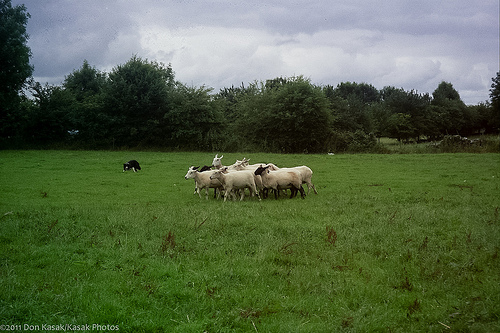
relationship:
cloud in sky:
[0, 0, 500, 82] [0, 1, 495, 108]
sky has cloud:
[0, 1, 495, 108] [383, 48, 449, 93]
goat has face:
[209, 167, 262, 202] [249, 164, 266, 174]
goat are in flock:
[184, 166, 226, 200] [182, 152, 319, 202]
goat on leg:
[209, 167, 262, 202] [223, 187, 229, 199]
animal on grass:
[117, 148, 153, 178] [24, 162, 471, 290]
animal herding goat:
[121, 160, 142, 172] [266, 162, 318, 194]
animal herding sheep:
[121, 160, 142, 172] [210, 166, 260, 200]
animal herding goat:
[121, 160, 142, 172] [254, 162, 306, 200]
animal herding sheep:
[121, 160, 142, 172] [292, 163, 313, 185]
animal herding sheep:
[121, 160, 142, 172] [210, 153, 225, 168]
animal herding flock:
[121, 160, 142, 172] [181, 152, 321, 202]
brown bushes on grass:
[154, 227, 185, 257] [5, 149, 495, 326]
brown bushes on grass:
[324, 223, 343, 250] [5, 149, 495, 326]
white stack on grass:
[325, 149, 338, 163] [328, 167, 470, 306]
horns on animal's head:
[211, 153, 224, 159] [205, 151, 227, 169]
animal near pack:
[118, 155, 143, 175] [183, 153, 318, 203]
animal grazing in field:
[121, 160, 142, 172] [1, 148, 499, 331]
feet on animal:
[120, 166, 141, 188] [113, 147, 142, 179]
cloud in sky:
[246, 51, 393, 82] [0, 1, 495, 108]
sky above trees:
[0, 1, 495, 108] [105, 60, 340, 132]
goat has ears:
[211, 153, 230, 169] [212, 153, 224, 161]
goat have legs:
[184, 166, 226, 200] [195, 182, 314, 203]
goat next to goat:
[184, 164, 213, 191] [209, 167, 262, 202]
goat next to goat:
[209, 167, 262, 202] [251, 162, 303, 194]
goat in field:
[184, 164, 213, 191] [119, 183, 443, 313]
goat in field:
[209, 167, 262, 202] [119, 183, 443, 313]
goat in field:
[251, 162, 303, 194] [119, 183, 443, 313]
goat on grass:
[184, 166, 226, 200] [5, 149, 495, 326]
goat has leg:
[266, 162, 315, 192] [310, 177, 320, 200]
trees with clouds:
[28, 56, 474, 152] [137, 21, 499, 77]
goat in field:
[206, 167, 260, 204] [118, 209, 456, 307]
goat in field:
[184, 166, 226, 200] [118, 209, 456, 307]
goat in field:
[206, 152, 230, 167] [118, 209, 456, 307]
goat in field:
[231, 160, 249, 172] [118, 209, 456, 307]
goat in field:
[242, 157, 257, 168] [118, 209, 456, 307]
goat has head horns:
[184, 166, 226, 200] [186, 160, 211, 172]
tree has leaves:
[220, 80, 415, 140] [10, 23, 39, 80]